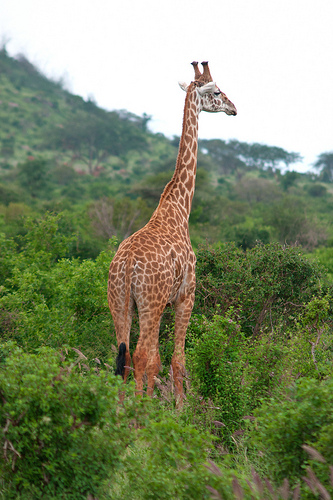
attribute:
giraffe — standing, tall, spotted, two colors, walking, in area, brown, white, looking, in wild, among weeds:
[99, 52, 246, 420]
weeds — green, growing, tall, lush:
[1, 317, 332, 498]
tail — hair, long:
[102, 246, 147, 379]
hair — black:
[109, 340, 129, 380]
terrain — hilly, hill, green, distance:
[1, 48, 332, 232]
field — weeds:
[1, 181, 330, 500]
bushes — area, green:
[175, 237, 332, 356]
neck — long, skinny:
[165, 99, 209, 224]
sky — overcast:
[5, 0, 332, 202]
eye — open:
[214, 91, 226, 102]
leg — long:
[172, 292, 199, 406]